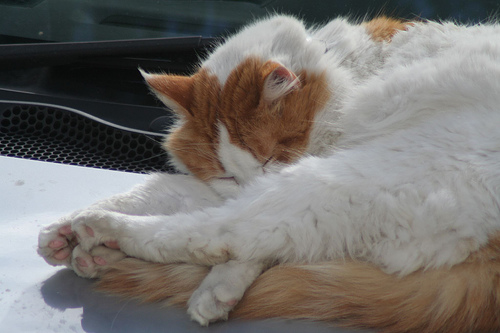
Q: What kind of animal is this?
A: A cat.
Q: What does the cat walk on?
A: Paws.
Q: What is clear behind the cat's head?
A: Glass.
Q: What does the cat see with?
A: Eyes.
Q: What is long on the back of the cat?
A: Tail.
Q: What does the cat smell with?
A: Nose.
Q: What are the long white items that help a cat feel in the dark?
A: Whiskers.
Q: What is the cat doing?
A: Sleeping.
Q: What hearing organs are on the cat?
A: Ears.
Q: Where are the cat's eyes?
A: Head.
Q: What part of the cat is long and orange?
A: Tail.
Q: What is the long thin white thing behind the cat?
A: A cord.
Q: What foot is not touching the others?
A: Right front.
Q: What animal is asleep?
A: A cat.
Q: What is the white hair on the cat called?
A: Fur.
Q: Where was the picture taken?
A: The picture was taken indoors.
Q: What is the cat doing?
A: The cat is sleeping.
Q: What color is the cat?
A: The cat is orange and white.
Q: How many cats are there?
A: 1 cat.